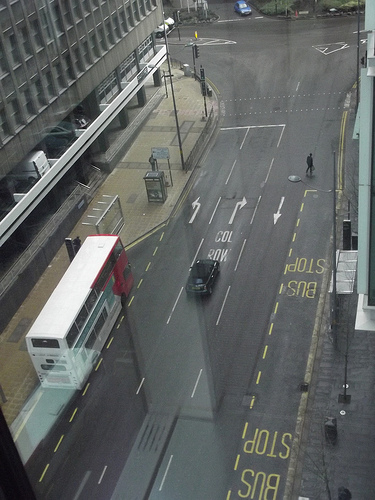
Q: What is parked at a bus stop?
A: A bus.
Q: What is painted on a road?
A: White lines.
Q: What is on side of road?
A: Double decker bus.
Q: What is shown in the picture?
A: Bus stop traffic lane.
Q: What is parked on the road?
A: The bus.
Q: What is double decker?
A: The bus.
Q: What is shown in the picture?
A: A bus.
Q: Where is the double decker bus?
A: On the street.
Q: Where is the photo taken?
A: In a city.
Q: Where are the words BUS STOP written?
A: On the road.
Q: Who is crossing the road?
A: A man.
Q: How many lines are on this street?
A: 42.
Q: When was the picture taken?
A: Before sunrise.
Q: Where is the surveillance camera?
A: Upper right side.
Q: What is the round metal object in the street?
A: Manhole cover.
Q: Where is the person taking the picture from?
A: Through a window In a building.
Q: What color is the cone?
A: Orange.